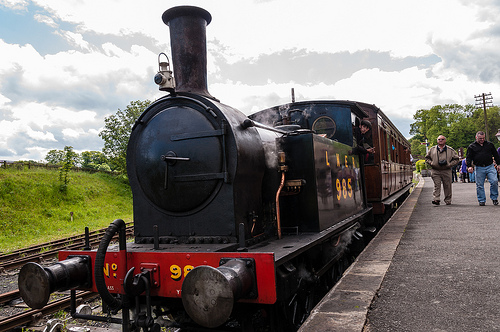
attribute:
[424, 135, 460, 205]
man — walking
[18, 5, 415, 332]
train — parked, black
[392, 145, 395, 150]
light — blue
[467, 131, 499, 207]
man — walking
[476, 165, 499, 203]
jeans — blue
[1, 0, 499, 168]
sky — cloudy, blue, white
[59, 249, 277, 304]
fender — red, yellow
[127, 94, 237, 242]
front — black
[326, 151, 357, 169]
letters — yellow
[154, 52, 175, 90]
lantern — little, white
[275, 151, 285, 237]
steam pipe — copper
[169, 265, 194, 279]
number — yellow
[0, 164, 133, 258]
grass — green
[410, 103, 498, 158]
trees — green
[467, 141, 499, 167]
shirt — black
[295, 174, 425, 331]
curb — stone